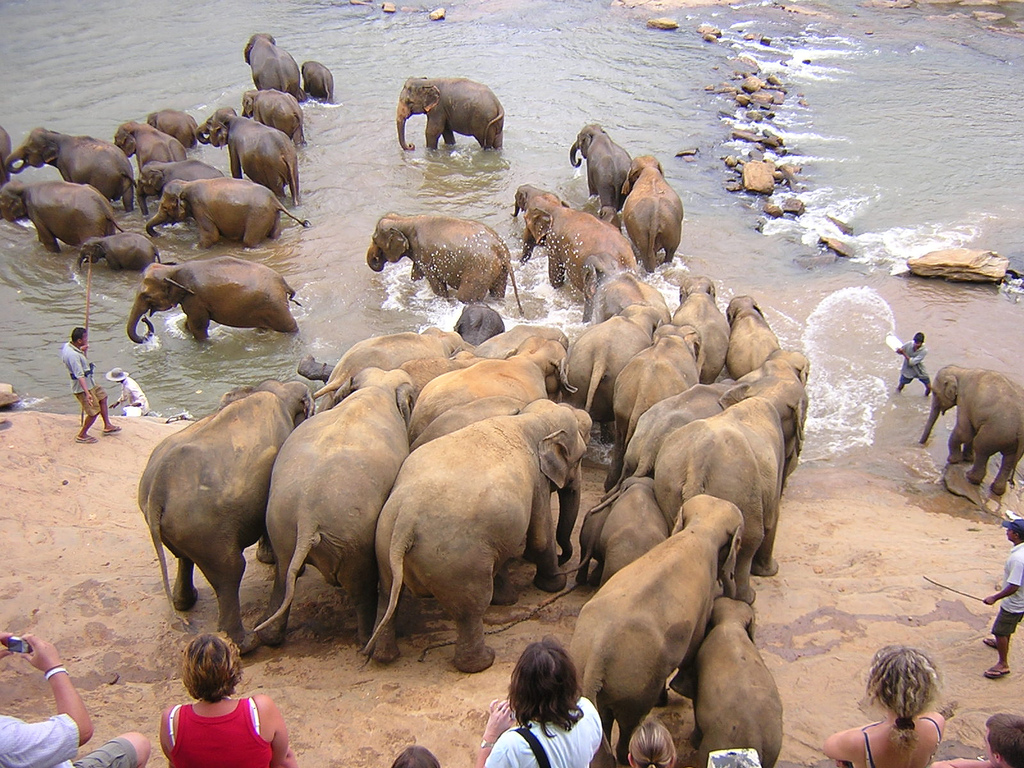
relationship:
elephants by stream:
[42, 229, 747, 694] [76, 18, 982, 462]